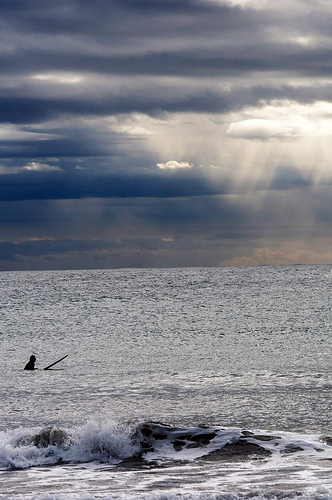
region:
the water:
[160, 427, 259, 498]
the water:
[196, 420, 233, 495]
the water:
[176, 420, 211, 493]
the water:
[206, 447, 230, 495]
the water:
[202, 461, 226, 493]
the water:
[190, 446, 217, 493]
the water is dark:
[175, 468, 184, 483]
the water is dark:
[196, 476, 209, 487]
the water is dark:
[205, 469, 211, 481]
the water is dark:
[198, 478, 209, 493]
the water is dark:
[193, 482, 205, 495]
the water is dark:
[207, 480, 218, 495]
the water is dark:
[190, 465, 208, 491]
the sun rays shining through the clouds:
[124, 99, 331, 243]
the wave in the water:
[3, 414, 331, 470]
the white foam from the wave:
[5, 426, 122, 462]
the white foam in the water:
[157, 437, 319, 466]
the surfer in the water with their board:
[24, 353, 69, 369]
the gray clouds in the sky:
[2, 3, 307, 90]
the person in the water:
[23, 354, 34, 369]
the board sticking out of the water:
[45, 352, 68, 370]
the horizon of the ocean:
[0, 242, 331, 289]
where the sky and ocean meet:
[1, 254, 331, 279]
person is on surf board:
[21, 345, 68, 373]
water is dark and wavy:
[0, 266, 331, 498]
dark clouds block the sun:
[0, 0, 331, 198]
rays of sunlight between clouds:
[218, 112, 330, 215]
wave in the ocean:
[0, 420, 330, 468]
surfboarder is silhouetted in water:
[21, 351, 69, 373]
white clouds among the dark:
[223, 100, 331, 144]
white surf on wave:
[2, 421, 329, 459]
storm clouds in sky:
[1, 0, 329, 197]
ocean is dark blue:
[0, 266, 331, 499]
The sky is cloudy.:
[30, 133, 307, 195]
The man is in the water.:
[22, 341, 89, 394]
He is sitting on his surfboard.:
[19, 342, 76, 386]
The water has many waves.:
[13, 272, 309, 495]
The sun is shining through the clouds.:
[86, 60, 330, 224]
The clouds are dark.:
[20, 23, 269, 250]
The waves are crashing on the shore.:
[24, 409, 282, 499]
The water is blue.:
[88, 307, 239, 404]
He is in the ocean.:
[19, 232, 301, 490]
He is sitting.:
[19, 342, 86, 397]